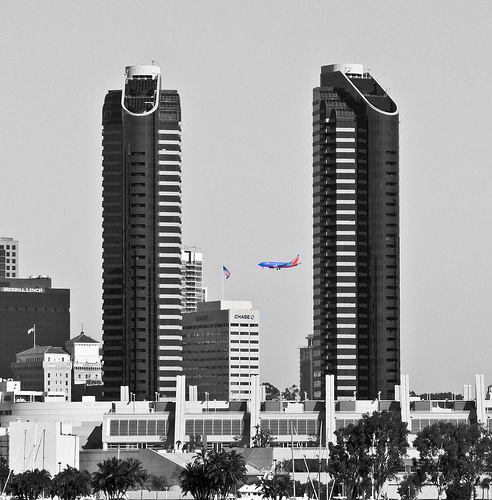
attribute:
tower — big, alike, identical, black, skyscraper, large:
[102, 65, 185, 401]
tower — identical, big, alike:
[314, 63, 401, 399]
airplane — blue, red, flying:
[258, 255, 300, 272]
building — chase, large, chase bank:
[182, 301, 259, 400]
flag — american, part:
[222, 266, 232, 280]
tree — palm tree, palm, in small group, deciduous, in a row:
[52, 464, 93, 499]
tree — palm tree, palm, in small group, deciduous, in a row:
[204, 450, 250, 499]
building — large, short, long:
[102, 374, 491, 453]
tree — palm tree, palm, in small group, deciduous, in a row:
[263, 473, 291, 499]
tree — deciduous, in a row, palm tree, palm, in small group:
[354, 409, 408, 499]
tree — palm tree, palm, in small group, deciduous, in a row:
[413, 423, 479, 499]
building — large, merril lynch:
[1, 278, 71, 380]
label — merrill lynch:
[3, 286, 45, 293]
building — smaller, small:
[10, 346, 72, 402]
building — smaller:
[65, 334, 103, 386]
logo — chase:
[235, 315, 256, 320]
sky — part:
[1, 0, 491, 397]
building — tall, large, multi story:
[0, 237, 19, 279]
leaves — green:
[205, 449, 247, 491]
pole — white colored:
[221, 266, 225, 301]